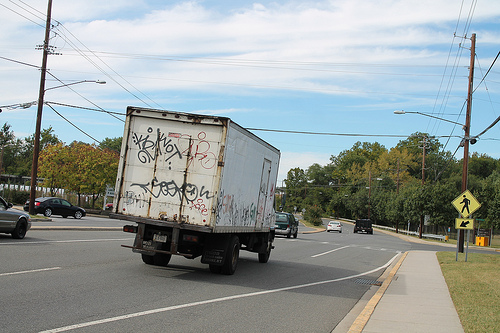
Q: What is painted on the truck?
A: Graffiti.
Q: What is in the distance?
A: Cars and trees.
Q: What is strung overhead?
A: Wires.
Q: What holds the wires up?
A: Poles.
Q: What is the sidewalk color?
A: Grey.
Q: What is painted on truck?
A: Graffiti.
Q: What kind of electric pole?
A: Wooden.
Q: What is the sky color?
A: Blue.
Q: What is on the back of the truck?
A: Graffiti..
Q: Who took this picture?
A: A pedestrian.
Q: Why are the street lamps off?
A: It's daytime.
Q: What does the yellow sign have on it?
A: Image of a person.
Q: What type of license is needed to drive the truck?
A: Commercial.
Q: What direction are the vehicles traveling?
A: Away from camera.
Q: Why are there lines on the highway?
A: To guide traffic.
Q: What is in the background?
A: Trees.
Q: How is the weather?
A: Partly cloudy.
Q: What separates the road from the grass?
A: The sidewalk.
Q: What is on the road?
A: Cars.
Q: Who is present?
A: Nobody.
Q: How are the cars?
A: In motion.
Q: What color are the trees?
A: Green.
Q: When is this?
A: Daytime.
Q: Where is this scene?
A: On the street.